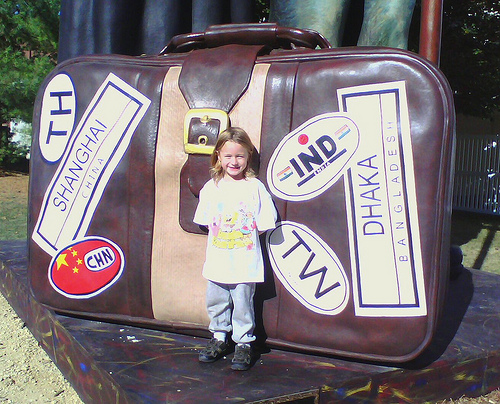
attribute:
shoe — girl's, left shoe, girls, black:
[234, 354, 253, 369]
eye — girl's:
[221, 154, 237, 158]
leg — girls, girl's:
[236, 282, 264, 340]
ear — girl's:
[244, 145, 257, 167]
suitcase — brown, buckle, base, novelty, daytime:
[60, 46, 413, 81]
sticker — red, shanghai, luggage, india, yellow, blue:
[276, 118, 342, 180]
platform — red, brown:
[57, 327, 133, 384]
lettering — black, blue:
[303, 147, 349, 169]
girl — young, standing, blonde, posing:
[204, 118, 277, 359]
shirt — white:
[199, 179, 248, 281]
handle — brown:
[113, 8, 276, 43]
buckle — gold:
[195, 103, 210, 118]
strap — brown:
[296, 40, 358, 51]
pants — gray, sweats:
[205, 292, 233, 305]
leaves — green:
[12, 23, 34, 40]